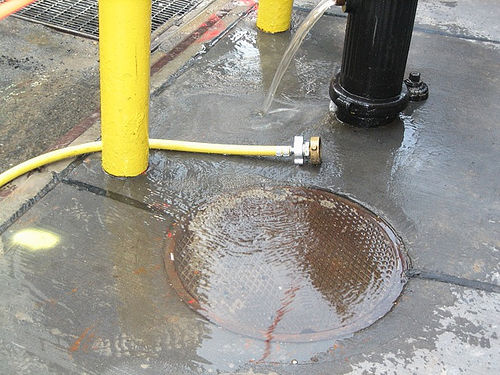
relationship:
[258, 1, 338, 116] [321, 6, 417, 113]
water in hydrant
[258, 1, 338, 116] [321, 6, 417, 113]
water from hydrant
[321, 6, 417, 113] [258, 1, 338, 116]
hydrant has water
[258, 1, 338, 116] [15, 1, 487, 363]
water on sidewalk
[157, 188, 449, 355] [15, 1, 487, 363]
manhole on sidewalk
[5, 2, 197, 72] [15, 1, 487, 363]
grate by sidewalk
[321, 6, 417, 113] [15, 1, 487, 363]
hydrant on sidewalk